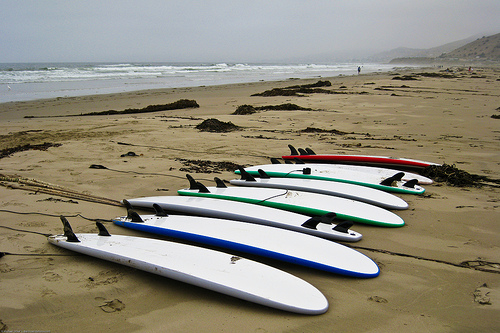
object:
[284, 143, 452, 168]
surfboard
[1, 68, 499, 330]
beach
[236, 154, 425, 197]
surfboard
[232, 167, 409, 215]
surfboard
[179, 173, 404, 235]
surfboard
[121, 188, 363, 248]
surfboard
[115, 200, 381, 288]
surfboard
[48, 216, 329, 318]
surfboard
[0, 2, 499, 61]
sky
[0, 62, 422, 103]
water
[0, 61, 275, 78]
wave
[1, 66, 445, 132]
shore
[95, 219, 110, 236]
knob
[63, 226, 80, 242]
knob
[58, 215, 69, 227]
knob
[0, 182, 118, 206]
tracks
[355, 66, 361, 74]
person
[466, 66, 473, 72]
person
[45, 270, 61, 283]
footprint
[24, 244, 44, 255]
footprint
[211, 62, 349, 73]
wave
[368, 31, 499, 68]
hill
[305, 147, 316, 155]
fin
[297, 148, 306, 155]
fin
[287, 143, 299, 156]
fin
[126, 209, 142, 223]
fin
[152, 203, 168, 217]
fin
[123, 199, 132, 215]
fin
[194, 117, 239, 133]
seaweed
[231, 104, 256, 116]
seaweed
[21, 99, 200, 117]
seaweed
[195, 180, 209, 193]
fin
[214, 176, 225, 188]
fin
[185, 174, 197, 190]
fin